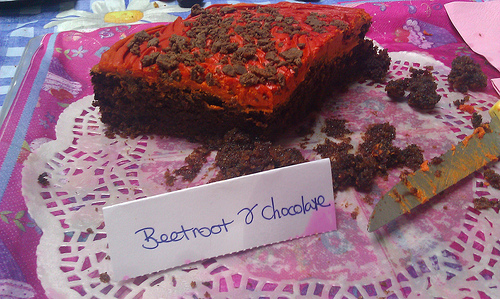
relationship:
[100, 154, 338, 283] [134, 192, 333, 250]
label with writing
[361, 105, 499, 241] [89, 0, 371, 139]
knife by cake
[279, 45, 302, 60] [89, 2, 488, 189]
chunk on cake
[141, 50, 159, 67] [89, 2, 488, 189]
chunk on cake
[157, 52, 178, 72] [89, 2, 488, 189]
chunk on cake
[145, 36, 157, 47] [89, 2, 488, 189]
chunk on cake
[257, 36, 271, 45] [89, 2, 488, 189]
chunk on cake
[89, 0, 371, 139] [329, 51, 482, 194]
cake has chunks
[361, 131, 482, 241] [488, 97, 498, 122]
knife has handle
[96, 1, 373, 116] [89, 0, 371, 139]
orange frosting on cake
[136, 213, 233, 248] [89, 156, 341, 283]
beetroot on sign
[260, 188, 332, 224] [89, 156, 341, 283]
chocolate on sign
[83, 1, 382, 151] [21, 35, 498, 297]
chocolate cake on doily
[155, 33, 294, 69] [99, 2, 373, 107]
bits on frosting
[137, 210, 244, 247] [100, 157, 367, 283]
inkprint on label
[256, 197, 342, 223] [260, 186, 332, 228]
inkprint reads chocolate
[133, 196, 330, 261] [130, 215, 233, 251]
blue inkprint reads beetroot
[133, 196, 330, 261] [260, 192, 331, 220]
blue inkprint reads chocolate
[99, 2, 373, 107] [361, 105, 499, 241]
frosting on knife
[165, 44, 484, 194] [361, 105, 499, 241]
crumbs on knife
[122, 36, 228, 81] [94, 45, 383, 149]
topping on cake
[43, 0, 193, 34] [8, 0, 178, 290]
daisy in tablecloth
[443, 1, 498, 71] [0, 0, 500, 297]
napkin on table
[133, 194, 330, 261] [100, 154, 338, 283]
blue inkprint on label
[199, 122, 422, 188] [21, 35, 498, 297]
crumbs on doily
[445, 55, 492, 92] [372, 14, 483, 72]
cupcake on tablecloth